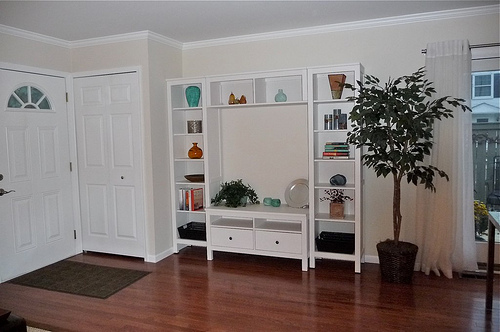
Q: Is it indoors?
A: Yes, it is indoors.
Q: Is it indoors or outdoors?
A: It is indoors.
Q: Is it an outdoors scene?
A: No, it is indoors.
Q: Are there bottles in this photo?
A: No, there are no bottles.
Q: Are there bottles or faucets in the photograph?
A: No, there are no bottles or faucets.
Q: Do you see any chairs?
A: No, there are no chairs.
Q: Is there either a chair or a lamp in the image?
A: No, there are no chairs or lamps.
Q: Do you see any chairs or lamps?
A: No, there are no chairs or lamps.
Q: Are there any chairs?
A: No, there are no chairs.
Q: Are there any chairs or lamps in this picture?
A: No, there are no chairs or lamps.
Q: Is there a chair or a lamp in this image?
A: No, there are no chairs or lamps.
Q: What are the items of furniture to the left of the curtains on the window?
A: The pieces of furniture are shelves.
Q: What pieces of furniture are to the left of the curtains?
A: The pieces of furniture are shelves.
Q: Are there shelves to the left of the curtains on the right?
A: Yes, there are shelves to the left of the curtains.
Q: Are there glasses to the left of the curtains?
A: No, there are shelves to the left of the curtains.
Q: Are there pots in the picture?
A: Yes, there is a pot.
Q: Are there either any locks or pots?
A: Yes, there is a pot.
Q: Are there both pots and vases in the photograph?
A: Yes, there are both a pot and vases.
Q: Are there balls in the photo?
A: No, there are no balls.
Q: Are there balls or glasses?
A: No, there are no balls or glasses.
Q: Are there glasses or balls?
A: No, there are no balls or glasses.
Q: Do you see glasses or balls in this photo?
A: No, there are no balls or glasses.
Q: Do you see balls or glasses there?
A: No, there are no balls or glasses.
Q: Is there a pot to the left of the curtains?
A: Yes, there is a pot to the left of the curtains.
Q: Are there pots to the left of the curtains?
A: Yes, there is a pot to the left of the curtains.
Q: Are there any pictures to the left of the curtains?
A: No, there is a pot to the left of the curtains.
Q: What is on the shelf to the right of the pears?
A: The pot is on the shelf.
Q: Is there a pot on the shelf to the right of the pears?
A: Yes, there is a pot on the shelf.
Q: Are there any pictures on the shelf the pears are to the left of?
A: No, there is a pot on the shelf.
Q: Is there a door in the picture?
A: Yes, there is a door.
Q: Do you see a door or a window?
A: Yes, there is a door.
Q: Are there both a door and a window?
A: Yes, there are both a door and a window.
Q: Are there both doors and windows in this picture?
A: Yes, there are both a door and a window.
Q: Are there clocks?
A: No, there are no clocks.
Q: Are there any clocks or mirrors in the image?
A: No, there are no clocks or mirrors.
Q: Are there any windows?
A: Yes, there is a window.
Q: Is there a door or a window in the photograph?
A: Yes, there is a window.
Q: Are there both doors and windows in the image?
A: Yes, there are both a window and a door.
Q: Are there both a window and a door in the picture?
A: Yes, there are both a window and a door.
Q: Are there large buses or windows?
A: Yes, there is a large window.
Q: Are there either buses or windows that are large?
A: Yes, the window is large.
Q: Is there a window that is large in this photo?
A: Yes, there is a large window.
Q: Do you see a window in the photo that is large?
A: Yes, there is a window that is large.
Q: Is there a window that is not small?
A: Yes, there is a large window.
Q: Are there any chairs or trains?
A: No, there are no chairs or trains.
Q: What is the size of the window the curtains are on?
A: The window is large.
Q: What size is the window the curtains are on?
A: The window is large.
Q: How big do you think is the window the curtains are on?
A: The window is large.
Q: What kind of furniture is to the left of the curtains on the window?
A: The piece of furniture is a shelf.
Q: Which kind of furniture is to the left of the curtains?
A: The piece of furniture is a shelf.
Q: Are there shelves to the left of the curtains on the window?
A: Yes, there is a shelf to the left of the curtains.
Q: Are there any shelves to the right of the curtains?
A: No, the shelf is to the left of the curtains.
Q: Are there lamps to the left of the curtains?
A: No, there is a shelf to the left of the curtains.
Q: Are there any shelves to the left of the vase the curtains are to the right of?
A: Yes, there is a shelf to the left of the vase.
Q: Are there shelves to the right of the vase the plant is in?
A: No, the shelf is to the left of the vase.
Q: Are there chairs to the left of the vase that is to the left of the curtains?
A: No, there is a shelf to the left of the vase.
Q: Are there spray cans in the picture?
A: No, there are no spray cans.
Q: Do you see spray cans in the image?
A: No, there are no spray cans.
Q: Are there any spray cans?
A: No, there are no spray cans.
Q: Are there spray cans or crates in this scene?
A: No, there are no spray cans or crates.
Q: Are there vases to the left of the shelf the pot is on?
A: Yes, there is a vase to the left of the shelf.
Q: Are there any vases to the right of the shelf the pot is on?
A: No, the vase is to the left of the shelf.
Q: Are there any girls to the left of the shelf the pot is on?
A: No, there is a vase to the left of the shelf.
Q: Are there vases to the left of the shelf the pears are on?
A: Yes, there is a vase to the left of the shelf.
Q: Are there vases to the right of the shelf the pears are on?
A: No, the vase is to the left of the shelf.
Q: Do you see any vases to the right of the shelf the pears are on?
A: No, the vase is to the left of the shelf.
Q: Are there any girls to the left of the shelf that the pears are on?
A: No, there is a vase to the left of the shelf.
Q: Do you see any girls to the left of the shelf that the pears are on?
A: No, there is a vase to the left of the shelf.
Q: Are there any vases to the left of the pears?
A: Yes, there is a vase to the left of the pears.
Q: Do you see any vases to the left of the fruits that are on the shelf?
A: Yes, there is a vase to the left of the pears.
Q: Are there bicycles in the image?
A: No, there are no bicycles.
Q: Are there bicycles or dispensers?
A: No, there are no bicycles or dispensers.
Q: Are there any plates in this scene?
A: Yes, there is a plate.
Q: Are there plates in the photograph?
A: Yes, there is a plate.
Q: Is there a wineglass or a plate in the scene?
A: Yes, there is a plate.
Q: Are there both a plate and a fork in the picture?
A: No, there is a plate but no forks.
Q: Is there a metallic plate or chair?
A: Yes, there is a metal plate.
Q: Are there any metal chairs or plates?
A: Yes, there is a metal plate.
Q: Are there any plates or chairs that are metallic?
A: Yes, the plate is metallic.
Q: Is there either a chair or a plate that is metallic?
A: Yes, the plate is metallic.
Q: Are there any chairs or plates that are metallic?
A: Yes, the plate is metallic.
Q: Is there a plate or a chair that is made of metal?
A: Yes, the plate is made of metal.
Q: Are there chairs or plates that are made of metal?
A: Yes, the plate is made of metal.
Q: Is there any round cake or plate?
A: Yes, there is a round plate.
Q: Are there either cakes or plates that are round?
A: Yes, the plate is round.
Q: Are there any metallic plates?
A: Yes, there is a metal plate.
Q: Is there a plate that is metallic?
A: Yes, there is a plate that is metallic.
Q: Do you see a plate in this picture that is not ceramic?
A: Yes, there is a metallic plate.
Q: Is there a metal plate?
A: Yes, there is a plate that is made of metal.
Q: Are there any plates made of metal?
A: Yes, there is a plate that is made of metal.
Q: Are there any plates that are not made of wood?
A: Yes, there is a plate that is made of metal.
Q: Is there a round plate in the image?
A: Yes, there is a round plate.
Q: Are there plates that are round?
A: Yes, there is a plate that is round.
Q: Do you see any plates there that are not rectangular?
A: Yes, there is a round plate.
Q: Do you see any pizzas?
A: No, there are no pizzas.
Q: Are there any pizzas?
A: No, there are no pizzas.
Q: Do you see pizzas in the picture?
A: No, there are no pizzas.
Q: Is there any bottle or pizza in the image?
A: No, there are no pizzas or bottles.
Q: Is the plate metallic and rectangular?
A: No, the plate is metallic but round.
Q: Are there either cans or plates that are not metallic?
A: No, there is a plate but it is metallic.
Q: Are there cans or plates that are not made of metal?
A: No, there is a plate but it is made of metal.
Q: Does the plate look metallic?
A: Yes, the plate is metallic.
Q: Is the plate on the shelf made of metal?
A: Yes, the plate is made of metal.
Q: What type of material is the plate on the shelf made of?
A: The plate is made of metal.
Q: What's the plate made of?
A: The plate is made of metal.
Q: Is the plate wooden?
A: No, the plate is metallic.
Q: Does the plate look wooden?
A: No, the plate is metallic.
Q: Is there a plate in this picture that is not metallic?
A: No, there is a plate but it is metallic.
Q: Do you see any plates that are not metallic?
A: No, there is a plate but it is metallic.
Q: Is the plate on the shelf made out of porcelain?
A: No, the plate is made of metal.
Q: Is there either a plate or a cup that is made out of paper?
A: No, there is a plate but it is made of metal.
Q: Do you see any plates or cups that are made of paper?
A: No, there is a plate but it is made of metal.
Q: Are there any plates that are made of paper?
A: No, there is a plate but it is made of metal.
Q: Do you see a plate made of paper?
A: No, there is a plate but it is made of metal.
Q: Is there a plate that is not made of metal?
A: No, there is a plate but it is made of metal.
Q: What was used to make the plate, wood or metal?
A: The plate is made of metal.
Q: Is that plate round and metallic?
A: Yes, the plate is round and metallic.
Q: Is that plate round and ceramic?
A: No, the plate is round but metallic.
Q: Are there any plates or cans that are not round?
A: No, there is a plate but it is round.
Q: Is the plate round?
A: Yes, the plate is round.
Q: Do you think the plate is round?
A: Yes, the plate is round.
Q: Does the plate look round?
A: Yes, the plate is round.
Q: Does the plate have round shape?
A: Yes, the plate is round.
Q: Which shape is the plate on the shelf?
A: The plate is round.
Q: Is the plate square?
A: No, the plate is round.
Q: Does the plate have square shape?
A: No, the plate is round.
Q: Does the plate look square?
A: No, the plate is round.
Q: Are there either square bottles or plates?
A: No, there is a plate but it is round.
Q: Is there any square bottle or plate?
A: No, there is a plate but it is round.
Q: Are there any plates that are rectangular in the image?
A: No, there is a plate but it is round.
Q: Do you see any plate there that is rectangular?
A: No, there is a plate but it is round.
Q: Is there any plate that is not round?
A: No, there is a plate but it is round.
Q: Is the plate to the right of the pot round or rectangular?
A: The plate is round.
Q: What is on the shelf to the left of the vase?
A: The plate is on the shelf.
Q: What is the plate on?
A: The plate is on the shelf.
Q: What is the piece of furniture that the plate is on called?
A: The piece of furniture is a shelf.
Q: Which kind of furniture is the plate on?
A: The plate is on the shelf.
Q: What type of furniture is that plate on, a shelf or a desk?
A: The plate is on a shelf.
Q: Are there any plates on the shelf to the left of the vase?
A: Yes, there is a plate on the shelf.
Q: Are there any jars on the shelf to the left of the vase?
A: No, there is a plate on the shelf.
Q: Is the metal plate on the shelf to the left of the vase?
A: Yes, the plate is on the shelf.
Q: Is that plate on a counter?
A: No, the plate is on the shelf.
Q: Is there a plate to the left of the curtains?
A: Yes, there is a plate to the left of the curtains.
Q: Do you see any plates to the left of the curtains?
A: Yes, there is a plate to the left of the curtains.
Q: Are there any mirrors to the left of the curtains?
A: No, there is a plate to the left of the curtains.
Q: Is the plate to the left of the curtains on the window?
A: Yes, the plate is to the left of the curtains.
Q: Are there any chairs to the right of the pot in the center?
A: No, there is a plate to the right of the pot.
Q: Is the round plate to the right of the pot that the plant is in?
A: Yes, the plate is to the right of the pot.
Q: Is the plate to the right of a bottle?
A: No, the plate is to the right of the pot.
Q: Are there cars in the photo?
A: No, there are no cars.